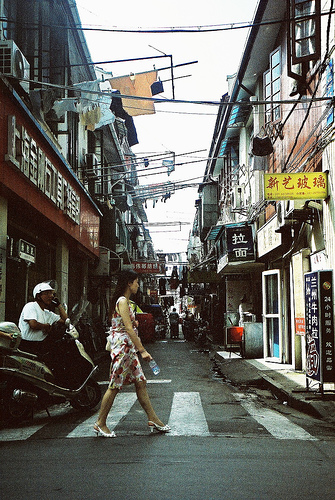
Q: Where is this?
A: This is at the sidewalk.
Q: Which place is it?
A: It is a sidewalk.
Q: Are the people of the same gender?
A: No, they are both male and female.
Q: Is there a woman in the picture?
A: Yes, there is a woman.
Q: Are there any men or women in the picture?
A: Yes, there is a woman.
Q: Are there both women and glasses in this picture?
A: No, there is a woman but no glasses.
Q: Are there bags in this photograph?
A: No, there are no bags.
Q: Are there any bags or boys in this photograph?
A: No, there are no bags or boys.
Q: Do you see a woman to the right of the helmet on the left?
A: Yes, there is a woman to the right of the helmet.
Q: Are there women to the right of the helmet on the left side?
A: Yes, there is a woman to the right of the helmet.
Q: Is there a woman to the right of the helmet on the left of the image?
A: Yes, there is a woman to the right of the helmet.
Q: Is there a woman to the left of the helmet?
A: No, the woman is to the right of the helmet.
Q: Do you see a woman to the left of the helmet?
A: No, the woman is to the right of the helmet.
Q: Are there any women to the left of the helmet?
A: No, the woman is to the right of the helmet.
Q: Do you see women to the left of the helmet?
A: No, the woman is to the right of the helmet.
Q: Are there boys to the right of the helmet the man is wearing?
A: No, there is a woman to the right of the helmet.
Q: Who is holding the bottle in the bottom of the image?
A: The woman is holding the bottle.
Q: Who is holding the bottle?
A: The woman is holding the bottle.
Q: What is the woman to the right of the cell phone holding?
A: The woman is holding the bottle.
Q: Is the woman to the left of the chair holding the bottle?
A: Yes, the woman is holding the bottle.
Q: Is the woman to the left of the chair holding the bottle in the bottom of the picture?
A: Yes, the woman is holding the bottle.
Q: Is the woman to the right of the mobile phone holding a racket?
A: No, the woman is holding the bottle.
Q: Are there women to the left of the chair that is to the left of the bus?
A: Yes, there is a woman to the left of the chair.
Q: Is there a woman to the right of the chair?
A: No, the woman is to the left of the chair.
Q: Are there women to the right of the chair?
A: No, the woman is to the left of the chair.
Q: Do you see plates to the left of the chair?
A: No, there is a woman to the left of the chair.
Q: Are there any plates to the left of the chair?
A: No, there is a woman to the left of the chair.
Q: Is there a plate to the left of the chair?
A: No, there is a woman to the left of the chair.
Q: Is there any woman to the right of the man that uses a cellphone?
A: Yes, there is a woman to the right of the man.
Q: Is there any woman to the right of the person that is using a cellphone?
A: Yes, there is a woman to the right of the man.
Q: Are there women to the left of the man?
A: No, the woman is to the right of the man.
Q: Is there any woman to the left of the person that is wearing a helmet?
A: No, the woman is to the right of the man.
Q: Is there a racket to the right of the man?
A: No, there is a woman to the right of the man.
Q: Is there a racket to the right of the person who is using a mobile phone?
A: No, there is a woman to the right of the man.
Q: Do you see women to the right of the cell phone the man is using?
A: Yes, there is a woman to the right of the cell phone.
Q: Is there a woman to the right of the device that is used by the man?
A: Yes, there is a woman to the right of the cell phone.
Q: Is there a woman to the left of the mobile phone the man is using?
A: No, the woman is to the right of the mobile phone.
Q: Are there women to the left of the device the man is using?
A: No, the woman is to the right of the mobile phone.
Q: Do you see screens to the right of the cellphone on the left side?
A: No, there is a woman to the right of the mobile phone.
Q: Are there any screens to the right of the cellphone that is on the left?
A: No, there is a woman to the right of the mobile phone.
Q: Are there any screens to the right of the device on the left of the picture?
A: No, there is a woman to the right of the mobile phone.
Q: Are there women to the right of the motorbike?
A: Yes, there is a woman to the right of the motorbike.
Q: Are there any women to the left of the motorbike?
A: No, the woman is to the right of the motorbike.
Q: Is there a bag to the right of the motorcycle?
A: No, there is a woman to the right of the motorcycle.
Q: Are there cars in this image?
A: No, there are no cars.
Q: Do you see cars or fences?
A: No, there are no cars or fences.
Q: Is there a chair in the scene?
A: Yes, there is a chair.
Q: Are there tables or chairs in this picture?
A: Yes, there is a chair.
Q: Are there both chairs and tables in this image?
A: No, there is a chair but no tables.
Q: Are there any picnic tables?
A: No, there are no picnic tables.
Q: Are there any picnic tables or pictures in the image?
A: No, there are no picnic tables or pictures.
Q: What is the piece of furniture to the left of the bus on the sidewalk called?
A: The piece of furniture is a chair.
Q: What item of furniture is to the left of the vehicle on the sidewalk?
A: The piece of furniture is a chair.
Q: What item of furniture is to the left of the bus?
A: The piece of furniture is a chair.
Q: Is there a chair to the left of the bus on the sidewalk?
A: Yes, there is a chair to the left of the bus.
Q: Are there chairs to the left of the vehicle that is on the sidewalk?
A: Yes, there is a chair to the left of the bus.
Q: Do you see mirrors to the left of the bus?
A: No, there is a chair to the left of the bus.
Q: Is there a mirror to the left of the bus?
A: No, there is a chair to the left of the bus.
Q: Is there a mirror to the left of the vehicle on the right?
A: No, there is a chair to the left of the bus.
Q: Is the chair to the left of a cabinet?
A: No, the chair is to the left of the bus.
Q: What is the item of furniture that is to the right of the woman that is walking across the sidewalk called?
A: The piece of furniture is a chair.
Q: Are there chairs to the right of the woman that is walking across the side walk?
A: Yes, there is a chair to the right of the woman.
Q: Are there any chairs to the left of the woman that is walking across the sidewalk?
A: No, the chair is to the right of the woman.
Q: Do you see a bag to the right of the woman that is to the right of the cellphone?
A: No, there is a chair to the right of the woman.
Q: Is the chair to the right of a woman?
A: Yes, the chair is to the right of a woman.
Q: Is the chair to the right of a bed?
A: No, the chair is to the right of a woman.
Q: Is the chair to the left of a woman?
A: No, the chair is to the right of a woman.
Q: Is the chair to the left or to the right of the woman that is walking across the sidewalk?
A: The chair is to the right of the woman.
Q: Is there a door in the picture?
A: Yes, there is a door.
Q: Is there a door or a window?
A: Yes, there is a door.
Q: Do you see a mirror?
A: No, there are no mirrors.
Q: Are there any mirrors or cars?
A: No, there are no mirrors or cars.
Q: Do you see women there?
A: Yes, there is a woman.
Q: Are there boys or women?
A: Yes, there is a woman.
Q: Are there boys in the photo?
A: No, there are no boys.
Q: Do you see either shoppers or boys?
A: No, there are no boys or shoppers.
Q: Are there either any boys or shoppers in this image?
A: No, there are no boys or shoppers.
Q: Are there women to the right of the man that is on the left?
A: Yes, there is a woman to the right of the man.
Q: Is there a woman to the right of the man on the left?
A: Yes, there is a woman to the right of the man.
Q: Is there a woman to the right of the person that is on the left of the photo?
A: Yes, there is a woman to the right of the man.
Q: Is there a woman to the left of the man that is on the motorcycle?
A: No, the woman is to the right of the man.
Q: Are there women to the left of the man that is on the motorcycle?
A: No, the woman is to the right of the man.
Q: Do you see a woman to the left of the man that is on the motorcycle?
A: No, the woman is to the right of the man.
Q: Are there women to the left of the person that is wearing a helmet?
A: No, the woman is to the right of the man.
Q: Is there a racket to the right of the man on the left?
A: No, there is a woman to the right of the man.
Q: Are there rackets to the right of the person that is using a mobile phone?
A: No, there is a woman to the right of the man.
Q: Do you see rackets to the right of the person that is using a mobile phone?
A: No, there is a woman to the right of the man.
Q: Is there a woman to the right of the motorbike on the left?
A: Yes, there is a woman to the right of the motorbike.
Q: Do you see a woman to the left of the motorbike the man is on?
A: No, the woman is to the right of the motorbike.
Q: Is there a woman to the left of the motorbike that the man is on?
A: No, the woman is to the right of the motorbike.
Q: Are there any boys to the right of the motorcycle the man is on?
A: No, there is a woman to the right of the motorcycle.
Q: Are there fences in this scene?
A: No, there are no fences.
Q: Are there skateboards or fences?
A: No, there are no fences or skateboards.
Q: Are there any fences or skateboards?
A: No, there are no fences or skateboards.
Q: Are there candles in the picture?
A: No, there are no candles.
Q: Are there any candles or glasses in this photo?
A: No, there are no candles or glasses.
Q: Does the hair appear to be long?
A: Yes, the hair is long.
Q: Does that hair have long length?
A: Yes, the hair is long.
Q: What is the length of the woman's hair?
A: The hair is long.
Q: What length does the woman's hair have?
A: The hair has long length.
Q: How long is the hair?
A: The hair is long.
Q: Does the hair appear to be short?
A: No, the hair is long.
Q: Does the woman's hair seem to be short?
A: No, the hair is long.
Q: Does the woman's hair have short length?
A: No, the hair is long.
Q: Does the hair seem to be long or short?
A: The hair is long.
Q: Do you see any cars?
A: No, there are no cars.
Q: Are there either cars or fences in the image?
A: No, there are no cars or fences.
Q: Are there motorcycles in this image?
A: Yes, there is a motorcycle.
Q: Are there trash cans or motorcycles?
A: Yes, there is a motorcycle.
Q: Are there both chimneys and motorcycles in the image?
A: No, there is a motorcycle but no chimneys.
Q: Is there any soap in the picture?
A: No, there are no soaps.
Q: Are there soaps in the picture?
A: No, there are no soaps.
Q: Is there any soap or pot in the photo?
A: No, there are no soaps or pots.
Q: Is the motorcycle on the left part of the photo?
A: Yes, the motorcycle is on the left of the image.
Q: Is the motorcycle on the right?
A: No, the motorcycle is on the left of the image.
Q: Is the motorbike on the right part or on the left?
A: The motorbike is on the left of the image.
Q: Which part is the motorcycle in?
A: The motorcycle is on the left of the image.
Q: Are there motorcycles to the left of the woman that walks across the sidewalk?
A: Yes, there is a motorcycle to the left of the woman.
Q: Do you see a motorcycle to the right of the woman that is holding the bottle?
A: No, the motorcycle is to the left of the woman.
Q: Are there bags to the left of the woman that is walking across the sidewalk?
A: No, there is a motorcycle to the left of the woman.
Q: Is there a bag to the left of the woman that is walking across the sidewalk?
A: No, there is a motorcycle to the left of the woman.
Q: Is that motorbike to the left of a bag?
A: No, the motorbike is to the left of a woman.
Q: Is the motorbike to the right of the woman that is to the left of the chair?
A: No, the motorbike is to the left of the woman.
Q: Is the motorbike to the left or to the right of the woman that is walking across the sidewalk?
A: The motorbike is to the left of the woman.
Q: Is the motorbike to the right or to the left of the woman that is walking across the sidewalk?
A: The motorbike is to the left of the woman.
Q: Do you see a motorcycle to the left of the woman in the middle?
A: Yes, there is a motorcycle to the left of the woman.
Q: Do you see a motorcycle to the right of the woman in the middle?
A: No, the motorcycle is to the left of the woman.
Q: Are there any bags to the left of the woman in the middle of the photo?
A: No, there is a motorcycle to the left of the woman.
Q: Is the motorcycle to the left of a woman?
A: Yes, the motorcycle is to the left of a woman.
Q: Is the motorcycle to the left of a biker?
A: No, the motorcycle is to the left of a woman.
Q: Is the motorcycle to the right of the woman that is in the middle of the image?
A: No, the motorcycle is to the left of the woman.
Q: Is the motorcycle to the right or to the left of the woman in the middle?
A: The motorcycle is to the left of the woman.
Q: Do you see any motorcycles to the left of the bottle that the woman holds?
A: Yes, there is a motorcycle to the left of the bottle.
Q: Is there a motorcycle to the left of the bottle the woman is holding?
A: Yes, there is a motorcycle to the left of the bottle.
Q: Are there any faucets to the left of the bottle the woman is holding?
A: No, there is a motorcycle to the left of the bottle.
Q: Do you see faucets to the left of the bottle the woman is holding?
A: No, there is a motorcycle to the left of the bottle.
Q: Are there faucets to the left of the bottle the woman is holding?
A: No, there is a motorcycle to the left of the bottle.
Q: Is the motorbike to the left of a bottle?
A: Yes, the motorbike is to the left of a bottle.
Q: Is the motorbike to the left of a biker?
A: No, the motorbike is to the left of a bottle.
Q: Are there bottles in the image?
A: Yes, there is a bottle.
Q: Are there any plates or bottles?
A: Yes, there is a bottle.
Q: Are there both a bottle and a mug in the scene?
A: No, there is a bottle but no mugs.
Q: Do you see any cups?
A: No, there are no cups.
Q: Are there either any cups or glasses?
A: No, there are no cups or glasses.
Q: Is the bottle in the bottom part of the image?
A: Yes, the bottle is in the bottom of the image.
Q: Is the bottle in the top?
A: No, the bottle is in the bottom of the image.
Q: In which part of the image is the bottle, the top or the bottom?
A: The bottle is in the bottom of the image.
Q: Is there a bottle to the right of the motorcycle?
A: Yes, there is a bottle to the right of the motorcycle.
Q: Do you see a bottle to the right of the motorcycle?
A: Yes, there is a bottle to the right of the motorcycle.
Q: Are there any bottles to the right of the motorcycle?
A: Yes, there is a bottle to the right of the motorcycle.